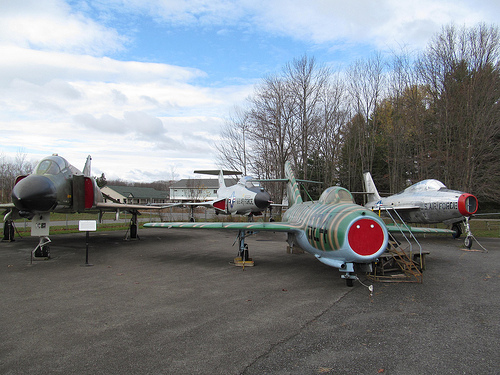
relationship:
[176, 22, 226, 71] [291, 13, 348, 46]
sky has clouds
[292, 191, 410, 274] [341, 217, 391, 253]
plane has front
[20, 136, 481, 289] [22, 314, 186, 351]
planes on concrete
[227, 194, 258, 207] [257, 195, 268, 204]
us air force in black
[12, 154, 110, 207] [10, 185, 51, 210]
plane has nose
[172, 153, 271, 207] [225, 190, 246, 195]
plane has star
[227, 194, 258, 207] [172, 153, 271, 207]
us air force on plane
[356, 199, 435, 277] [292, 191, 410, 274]
stairs to plane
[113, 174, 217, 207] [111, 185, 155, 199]
buildings has roof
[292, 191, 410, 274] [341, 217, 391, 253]
plane has tip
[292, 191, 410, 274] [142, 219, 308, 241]
plane has wing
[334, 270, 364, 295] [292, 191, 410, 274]
wheel on plane